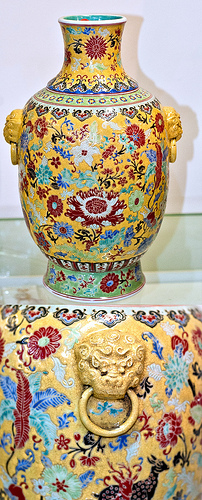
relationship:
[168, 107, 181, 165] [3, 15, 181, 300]
yellow emblem on vase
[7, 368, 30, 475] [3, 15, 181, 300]
red feather on vase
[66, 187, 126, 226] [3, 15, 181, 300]
red and white flower on vase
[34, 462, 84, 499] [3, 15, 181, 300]
flower on vase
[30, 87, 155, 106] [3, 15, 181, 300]
pattern around vase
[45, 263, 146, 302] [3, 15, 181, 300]
base of vase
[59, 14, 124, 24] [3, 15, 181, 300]
opening on top of vase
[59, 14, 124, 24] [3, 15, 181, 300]
opening of vase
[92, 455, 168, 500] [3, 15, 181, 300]
deer on vase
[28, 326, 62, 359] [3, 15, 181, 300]
flower on vase